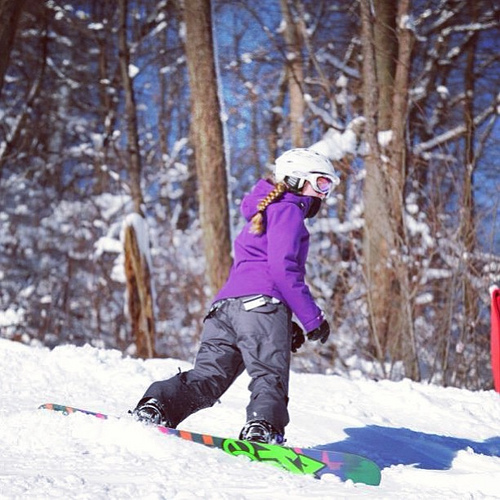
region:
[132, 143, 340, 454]
person wearing purple ski jacket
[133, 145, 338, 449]
person wearing white ski helmet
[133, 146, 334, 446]
person standing on snowboard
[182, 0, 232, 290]
brown tree trunk behind person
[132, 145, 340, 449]
person wearing gray ski pants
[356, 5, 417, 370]
tree is next to tree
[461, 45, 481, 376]
tree is next to tree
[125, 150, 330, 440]
girl with blonde braided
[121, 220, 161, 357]
tree is next to tree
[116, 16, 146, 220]
tree is next to tree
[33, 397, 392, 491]
snowboard in the snow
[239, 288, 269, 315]
card in girl's pocket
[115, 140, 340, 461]
girl on a snowboard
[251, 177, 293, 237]
girl's blonde braided hair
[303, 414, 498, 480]
shadow of a girl in the snow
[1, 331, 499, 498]
snow covered ground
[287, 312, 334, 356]
girl's black gloves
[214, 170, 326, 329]
girl's purple hooded jacket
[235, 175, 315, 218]
hood on a purple jacket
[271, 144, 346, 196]
girl's white ski helmet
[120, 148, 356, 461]
person wearing white helmet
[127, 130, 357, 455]
person wearing purple jacket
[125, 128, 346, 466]
person wearing a pair of gloves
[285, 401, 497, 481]
shadow of a person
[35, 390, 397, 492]
a snowboard used by people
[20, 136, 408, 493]
person is snow boarding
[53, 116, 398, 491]
person wearing a dark ski pants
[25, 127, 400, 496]
woman is snow boarding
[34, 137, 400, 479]
person has braided hair and pony tail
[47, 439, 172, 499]
a snowy field plain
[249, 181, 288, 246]
The girl has a pony tail.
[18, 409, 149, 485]
The snow is powder like.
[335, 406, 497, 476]
The shadow of the snowboarder.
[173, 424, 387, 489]
The snow board is purple with a green design.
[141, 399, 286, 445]
Black snowboarding boots on the girl's feet.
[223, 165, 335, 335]
The girl is wearing a purple sweater.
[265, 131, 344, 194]
The girl is wearing a white helmet with goggles.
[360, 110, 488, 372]
Several dead trees in the background.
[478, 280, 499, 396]
A red object at the side of the image.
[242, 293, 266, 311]
A small card on the girl's waist.